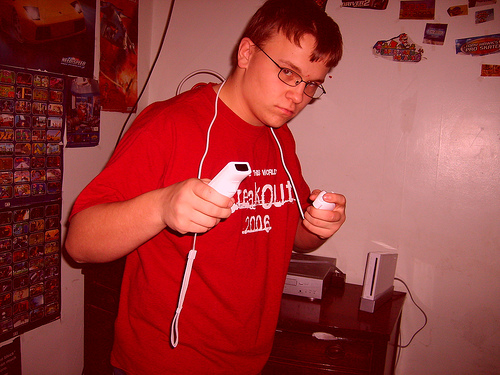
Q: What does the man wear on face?
A: Glasses.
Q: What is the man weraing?
A: Red shirt.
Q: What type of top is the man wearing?
A: Red shirt.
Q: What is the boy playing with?
A: Video game remote control.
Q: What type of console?
A: White video game system.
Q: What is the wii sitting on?
A: A dresser.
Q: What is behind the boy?
A: A dresser with electronics on top.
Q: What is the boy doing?
A: Posing.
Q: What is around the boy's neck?
A: A cord.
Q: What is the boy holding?
A: A wii remote.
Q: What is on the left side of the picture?
A: Posters on the wall.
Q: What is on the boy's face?
A: Glasses.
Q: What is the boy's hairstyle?
A: Short blond.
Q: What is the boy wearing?
A: A red shirt.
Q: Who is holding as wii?
A: A young man.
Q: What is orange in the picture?
A: A shirt.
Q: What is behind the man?
A: A desk.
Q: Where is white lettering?
A: On the man's the shirt.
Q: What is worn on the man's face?
A: Eyeglasses.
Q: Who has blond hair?
A: The man.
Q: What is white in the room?
A: The wall.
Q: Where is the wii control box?
A: The desk.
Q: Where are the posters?
A: The wall.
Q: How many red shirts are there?
A: One.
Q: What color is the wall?
A: White.